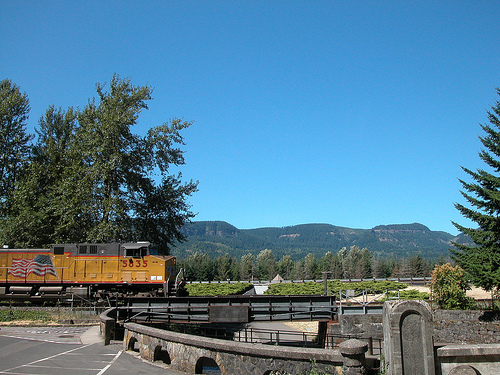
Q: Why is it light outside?
A: Sun.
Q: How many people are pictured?
A: 0.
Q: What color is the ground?
A: Grey.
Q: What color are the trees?
A: Green.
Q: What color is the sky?
A: Blue.